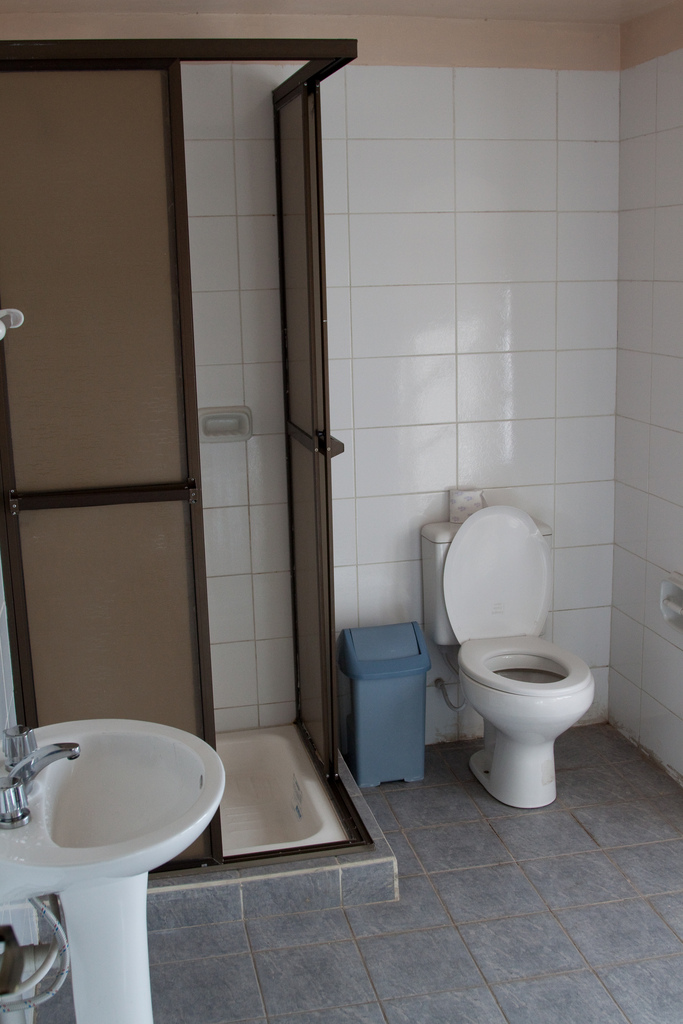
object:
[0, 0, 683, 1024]
bathroom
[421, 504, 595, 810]
toilet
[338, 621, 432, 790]
garbage can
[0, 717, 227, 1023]
sink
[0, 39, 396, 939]
shower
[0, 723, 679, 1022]
flooring